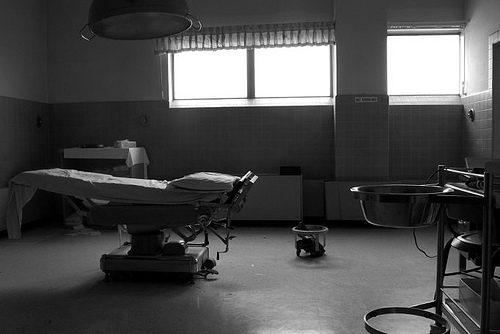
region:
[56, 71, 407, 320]
a mental hospital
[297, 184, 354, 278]
a circle in the room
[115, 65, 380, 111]
windows in the room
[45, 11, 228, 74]
a light above the bed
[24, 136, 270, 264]
a bed at the room of the hospital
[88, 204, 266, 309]
the bottom of the bed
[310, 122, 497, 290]
the sink in the room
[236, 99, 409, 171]
the side of the room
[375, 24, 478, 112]
the window that light sines through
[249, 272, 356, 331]
the hard ground of the room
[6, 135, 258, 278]
operating table with pillow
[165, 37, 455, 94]
three windows with light streaming in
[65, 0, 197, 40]
large light for operating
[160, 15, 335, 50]
ruffled window treatment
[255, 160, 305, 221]
vent and furnace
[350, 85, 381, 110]
no smoking sign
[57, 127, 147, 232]
table with operating instruments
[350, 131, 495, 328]
bowl, cord, and other equipment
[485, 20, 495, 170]
top part of doorway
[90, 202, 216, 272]
controls for adjusting bed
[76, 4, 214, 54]
light fixture on the ceiling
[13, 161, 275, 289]
operating table in a surgery room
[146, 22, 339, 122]
window in a surgery room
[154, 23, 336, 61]
curtains hanging from window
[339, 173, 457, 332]
disposal bin in a surgery room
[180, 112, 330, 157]
tile wall in a surgery room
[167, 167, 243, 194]
pillow on a hospital bed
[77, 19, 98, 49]
handle of a light fixture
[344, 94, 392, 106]
no smoking sign on the wall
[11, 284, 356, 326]
floor of a surgery room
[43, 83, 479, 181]
There are square tiles halfway up the walls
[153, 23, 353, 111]
The top of the window has small curtains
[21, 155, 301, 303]
A medical chair has a white pillow and white sheet on top of it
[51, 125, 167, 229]
There is a table with a sterile field sheet resting on top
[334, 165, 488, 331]
A metal basin sits in a holder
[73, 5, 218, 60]
Large light with handles on either side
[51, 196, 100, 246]
Towels lay on the floor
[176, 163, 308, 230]
A white cabinet with a black box on top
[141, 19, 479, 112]
Three square windows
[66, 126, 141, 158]
Supplies rest on top of the white sheet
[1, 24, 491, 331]
a hospital room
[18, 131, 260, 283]
a hospital bed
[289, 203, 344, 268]
a little cage in the corner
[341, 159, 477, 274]
a sink in the corner of the room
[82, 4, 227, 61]
light above the patients bed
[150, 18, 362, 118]
a window that is shinning through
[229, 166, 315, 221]
what appears to be an AC area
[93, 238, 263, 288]
the base of the bed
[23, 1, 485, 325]
a creepy photo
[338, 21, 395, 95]
a part of the wall